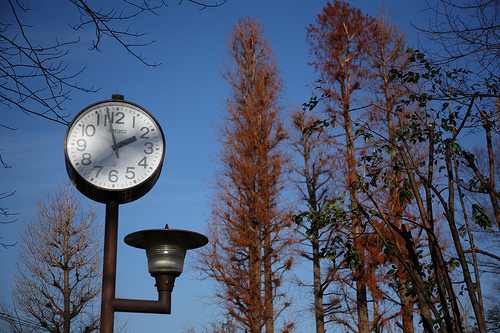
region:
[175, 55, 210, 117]
The sky is blue.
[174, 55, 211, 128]
The sky is clear.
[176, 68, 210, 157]
The sky is a rich color.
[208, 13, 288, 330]
The tree is tall.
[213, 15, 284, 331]
The tree is brown.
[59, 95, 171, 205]
A clock.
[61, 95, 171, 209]
The clock face is white.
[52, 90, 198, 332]
A clock on a post.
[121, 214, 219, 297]
A light on a post.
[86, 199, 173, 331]
The post is made of metal.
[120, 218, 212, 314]
street light on pole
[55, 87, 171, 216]
clock specifying 1:58 p.m.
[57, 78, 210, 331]
clock and street light on same pole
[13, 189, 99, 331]
tree that is leafless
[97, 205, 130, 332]
a dark colored post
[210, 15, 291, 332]
two tall skinny trees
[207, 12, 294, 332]
two tall thin trees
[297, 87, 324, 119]
green leaves hanging in the air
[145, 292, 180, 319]
a right angle of a pole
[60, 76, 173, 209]
clock with arabic numbers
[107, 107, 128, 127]
The number 12 on the clock.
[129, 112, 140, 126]
The number 1 on the clock.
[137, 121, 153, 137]
The number 2 on the clock.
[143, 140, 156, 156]
The number 3 on the clock.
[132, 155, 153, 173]
The number 4 on the clock.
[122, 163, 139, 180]
The number 5 on the clock.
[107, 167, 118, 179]
The number 6 on the clock.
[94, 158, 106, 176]
The number 7 on the clock.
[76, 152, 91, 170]
The number 8 on the clock.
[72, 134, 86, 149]
The number 9 on the clock.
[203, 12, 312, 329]
The tree is tall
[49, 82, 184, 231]
The clock is round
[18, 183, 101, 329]
The tree is bare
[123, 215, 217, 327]
The light is off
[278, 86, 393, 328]
The tree is green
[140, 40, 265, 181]
The sky is blue and clear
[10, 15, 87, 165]
The tree branches are bare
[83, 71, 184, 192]
It is almost 2:00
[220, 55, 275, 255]
The tree is brown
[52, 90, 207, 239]
The clock is white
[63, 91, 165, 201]
a clock on a street light pole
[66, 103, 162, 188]
the clock time displayed is 1:58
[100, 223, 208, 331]
a street light on a pole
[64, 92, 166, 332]
the clock is on a pole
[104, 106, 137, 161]
the clock hands are black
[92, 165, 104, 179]
the numbers on the clock are black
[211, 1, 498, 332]
pinetrees behind the clock and light post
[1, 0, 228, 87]
blue sky's without any clouds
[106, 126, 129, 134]
the brand name on the clock is Seiko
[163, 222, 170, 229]
the screw to remove the street light cover